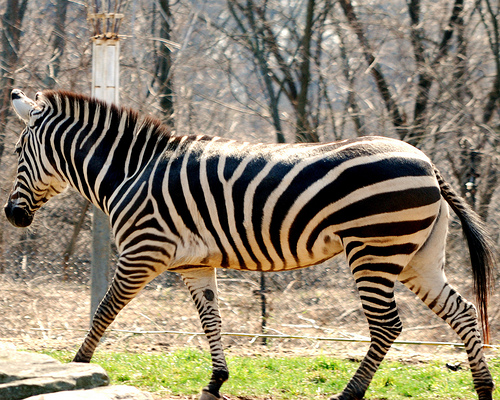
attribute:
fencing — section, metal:
[15, 232, 122, 321]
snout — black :
[0, 202, 33, 227]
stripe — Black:
[6, 102, 490, 385]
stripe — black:
[356, 286, 393, 298]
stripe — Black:
[351, 241, 419, 258]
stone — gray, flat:
[0, 347, 111, 397]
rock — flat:
[0, 348, 153, 398]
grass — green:
[27, 349, 497, 398]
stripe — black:
[259, 151, 288, 264]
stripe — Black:
[404, 282, 419, 291]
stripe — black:
[327, 192, 383, 252]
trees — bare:
[336, 3, 480, 138]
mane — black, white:
[36, 84, 182, 139]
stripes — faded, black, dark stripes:
[368, 239, 396, 339]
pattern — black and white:
[139, 160, 411, 251]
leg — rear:
[399, 186, 491, 398]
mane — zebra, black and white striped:
[26, 69, 193, 156]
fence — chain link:
[6, 176, 491, 326]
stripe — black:
[112, 109, 123, 208]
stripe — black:
[113, 102, 129, 212]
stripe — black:
[105, 98, 126, 232]